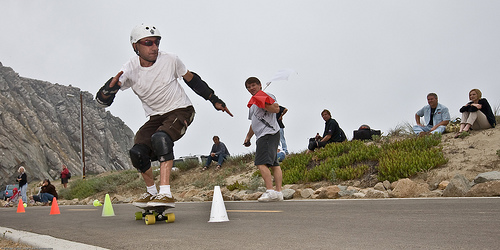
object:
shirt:
[114, 52, 192, 118]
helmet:
[127, 23, 161, 44]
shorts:
[127, 104, 199, 173]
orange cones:
[49, 197, 64, 215]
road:
[0, 194, 499, 250]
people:
[453, 88, 495, 139]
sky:
[0, 0, 500, 160]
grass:
[50, 121, 441, 201]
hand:
[209, 101, 237, 119]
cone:
[98, 193, 118, 217]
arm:
[92, 91, 120, 108]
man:
[410, 92, 450, 135]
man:
[308, 108, 348, 149]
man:
[199, 134, 230, 173]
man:
[31, 178, 61, 206]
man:
[58, 165, 71, 188]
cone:
[203, 185, 231, 223]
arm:
[412, 113, 422, 123]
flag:
[244, 92, 275, 110]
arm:
[177, 59, 221, 101]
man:
[241, 76, 284, 202]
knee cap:
[151, 126, 175, 168]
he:
[94, 21, 235, 205]